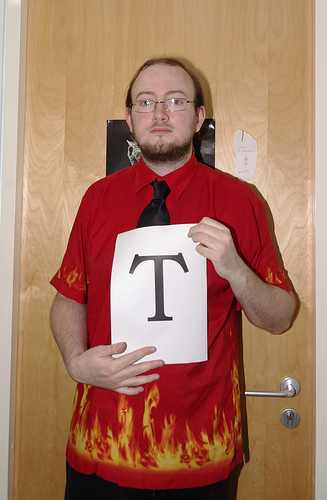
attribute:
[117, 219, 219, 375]
paper — piece, white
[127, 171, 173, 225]
tie — black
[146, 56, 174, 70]
hair — brown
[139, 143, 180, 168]
hair — facial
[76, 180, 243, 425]
shirt — red, yellow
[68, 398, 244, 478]
flames — yellow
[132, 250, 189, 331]
t — black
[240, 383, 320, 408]
handle — silver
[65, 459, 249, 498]
pants — black